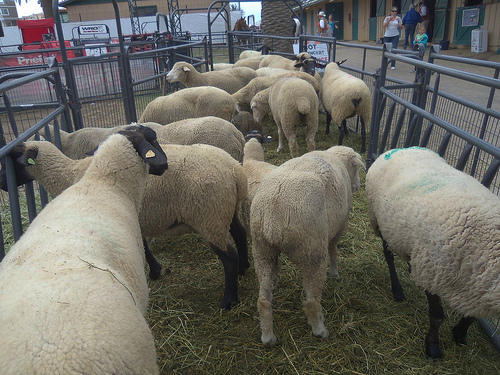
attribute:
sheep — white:
[249, 80, 337, 156]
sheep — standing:
[320, 57, 382, 148]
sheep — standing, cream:
[159, 58, 253, 92]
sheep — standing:
[250, 137, 378, 349]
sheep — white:
[2, 123, 170, 374]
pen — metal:
[52, 1, 140, 130]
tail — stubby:
[292, 99, 317, 115]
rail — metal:
[384, 49, 498, 88]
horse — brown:
[231, 14, 261, 42]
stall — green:
[352, 4, 360, 39]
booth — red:
[21, 19, 60, 49]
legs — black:
[339, 121, 376, 148]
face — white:
[165, 61, 188, 83]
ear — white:
[183, 66, 192, 77]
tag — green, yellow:
[25, 160, 41, 167]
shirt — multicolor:
[416, 36, 427, 44]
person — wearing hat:
[314, 9, 338, 47]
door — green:
[368, 15, 380, 40]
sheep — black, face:
[2, 137, 248, 315]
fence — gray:
[303, 35, 338, 61]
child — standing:
[413, 26, 436, 70]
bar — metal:
[127, 47, 176, 85]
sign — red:
[5, 45, 63, 70]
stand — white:
[471, 26, 489, 55]